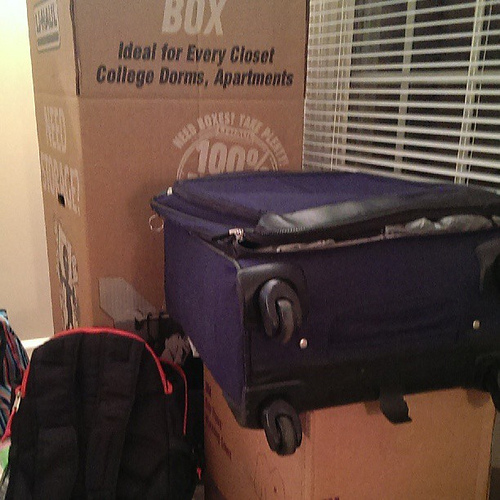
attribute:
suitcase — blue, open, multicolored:
[136, 126, 472, 422]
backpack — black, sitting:
[21, 318, 211, 481]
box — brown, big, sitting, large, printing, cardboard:
[24, 8, 306, 179]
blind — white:
[297, 12, 487, 137]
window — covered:
[305, 61, 455, 140]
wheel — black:
[261, 289, 306, 352]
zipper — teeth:
[367, 221, 421, 261]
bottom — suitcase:
[202, 352, 469, 495]